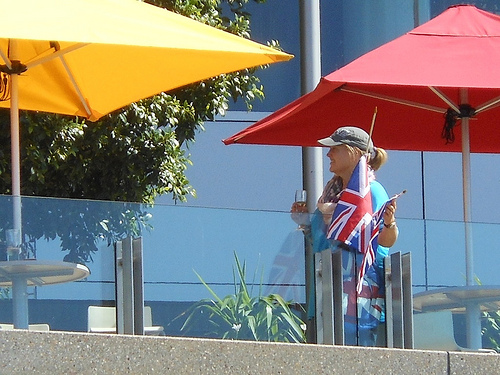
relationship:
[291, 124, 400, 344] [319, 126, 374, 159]
woman wearing a baseball cap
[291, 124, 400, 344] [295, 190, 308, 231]
woman holding champagne flute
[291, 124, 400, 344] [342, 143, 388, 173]
woman has hair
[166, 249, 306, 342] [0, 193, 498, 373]
plant on patio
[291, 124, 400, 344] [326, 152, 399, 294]
woman holding flags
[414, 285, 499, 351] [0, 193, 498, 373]
table on patio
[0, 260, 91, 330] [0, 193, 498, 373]
table on patio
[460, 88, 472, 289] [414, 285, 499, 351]
pole on table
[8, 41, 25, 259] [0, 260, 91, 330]
pole on table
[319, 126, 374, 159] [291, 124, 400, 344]
baseball cap on woman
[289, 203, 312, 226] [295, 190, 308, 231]
hand holding champagne flute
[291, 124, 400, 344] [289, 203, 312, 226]
woman has a hand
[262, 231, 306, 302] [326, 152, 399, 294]
reflection of flags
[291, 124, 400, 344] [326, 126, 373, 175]
woman has a head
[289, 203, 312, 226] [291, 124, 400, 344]
hand on woman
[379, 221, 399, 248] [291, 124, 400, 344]
arm of woman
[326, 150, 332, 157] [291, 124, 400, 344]
nose on woman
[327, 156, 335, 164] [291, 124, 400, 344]
mouth on woman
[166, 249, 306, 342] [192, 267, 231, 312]
plant has a leaf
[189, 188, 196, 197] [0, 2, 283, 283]
leaf on tree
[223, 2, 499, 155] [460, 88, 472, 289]
umbrella on pole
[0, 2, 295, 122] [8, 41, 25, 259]
umbrella on pole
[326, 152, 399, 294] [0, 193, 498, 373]
flags on patio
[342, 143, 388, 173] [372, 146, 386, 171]
hair in a pony tail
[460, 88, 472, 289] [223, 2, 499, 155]
pole on umbrella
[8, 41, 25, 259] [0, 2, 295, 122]
pole on umbrella